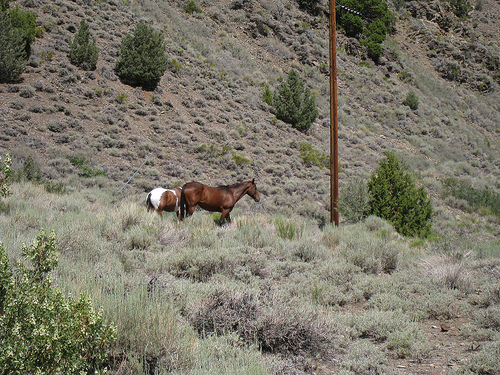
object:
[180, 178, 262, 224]
horse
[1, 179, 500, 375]
grass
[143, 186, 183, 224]
horse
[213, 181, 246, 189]
mane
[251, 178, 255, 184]
ear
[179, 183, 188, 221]
tail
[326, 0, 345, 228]
post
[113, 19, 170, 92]
bush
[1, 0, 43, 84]
bushes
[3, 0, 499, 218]
hill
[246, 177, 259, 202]
head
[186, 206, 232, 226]
legs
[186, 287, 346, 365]
bush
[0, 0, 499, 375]
vegetation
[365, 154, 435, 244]
tree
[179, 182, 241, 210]
body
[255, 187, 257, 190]
eye